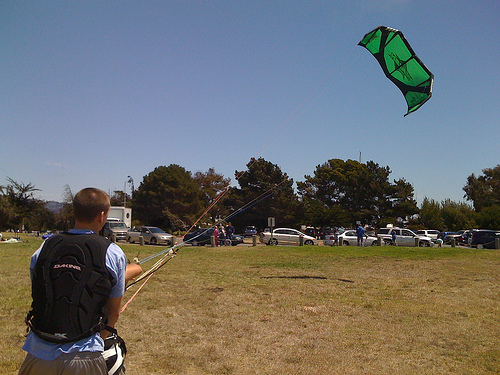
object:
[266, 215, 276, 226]
back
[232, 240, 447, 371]
ground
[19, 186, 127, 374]
man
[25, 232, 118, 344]
chest protector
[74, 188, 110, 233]
head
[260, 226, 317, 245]
car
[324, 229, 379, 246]
car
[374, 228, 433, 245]
car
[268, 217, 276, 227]
sign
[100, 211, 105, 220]
ear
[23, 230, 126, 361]
shirt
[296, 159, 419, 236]
tree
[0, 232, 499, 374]
grass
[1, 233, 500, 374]
ground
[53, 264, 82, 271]
lettering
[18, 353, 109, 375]
shorts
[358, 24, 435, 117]
kite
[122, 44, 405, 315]
strings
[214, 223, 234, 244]
family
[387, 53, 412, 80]
design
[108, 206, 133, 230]
truck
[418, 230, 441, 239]
car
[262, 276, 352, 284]
shadow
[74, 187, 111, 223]
blonde hair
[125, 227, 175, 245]
car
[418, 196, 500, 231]
trees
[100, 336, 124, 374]
bookbag